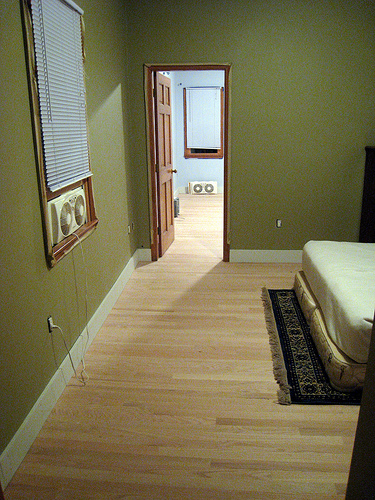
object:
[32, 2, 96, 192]
window shades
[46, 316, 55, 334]
plug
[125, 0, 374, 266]
wall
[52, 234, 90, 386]
cord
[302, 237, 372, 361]
mattress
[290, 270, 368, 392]
boxspring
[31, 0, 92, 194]
blinds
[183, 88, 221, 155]
window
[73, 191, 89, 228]
electric fan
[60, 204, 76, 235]
electric fan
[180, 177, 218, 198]
fan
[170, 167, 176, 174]
door knob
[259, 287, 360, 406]
rug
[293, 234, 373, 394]
bed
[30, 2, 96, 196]
window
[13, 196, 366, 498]
floor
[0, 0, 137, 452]
wall